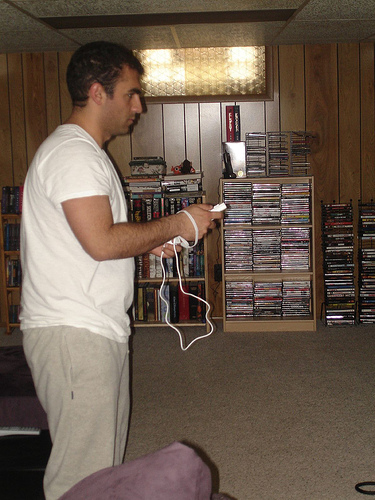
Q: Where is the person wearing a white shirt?
A: On the left.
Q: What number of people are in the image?
A: One.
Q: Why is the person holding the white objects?
A: Playing video games.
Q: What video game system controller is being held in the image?
A: Wii.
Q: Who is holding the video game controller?
A: The man.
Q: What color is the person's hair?
A: Black.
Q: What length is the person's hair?
A: Short.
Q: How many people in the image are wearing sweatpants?
A: One.